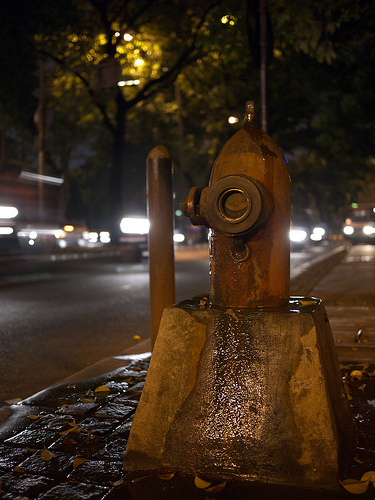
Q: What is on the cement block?
A: A rusted fire hydrant.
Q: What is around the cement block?
A: Water.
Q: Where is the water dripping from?
A: The cement block.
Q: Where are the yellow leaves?
A: On the sidewalk.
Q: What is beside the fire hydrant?
A: The street.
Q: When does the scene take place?
A: At night time.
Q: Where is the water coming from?
A: The fire hydrant.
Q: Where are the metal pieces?
A: On the fire hydrant.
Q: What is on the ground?
A: Yellow leaves.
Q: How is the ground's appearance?
A: Wet.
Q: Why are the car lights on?
A: Dark outside.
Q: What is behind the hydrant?
A: A metal pole.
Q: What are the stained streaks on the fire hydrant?
A: Water leaking on to base of fire hydrant.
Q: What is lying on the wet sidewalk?
A: Yellow leaves.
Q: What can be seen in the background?
A: Lights from businesses.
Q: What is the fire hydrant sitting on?
A: A cement base.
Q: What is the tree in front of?
A: Business signs.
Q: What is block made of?
A: Cement.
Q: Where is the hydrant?
A: On block.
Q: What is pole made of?
A: Metal.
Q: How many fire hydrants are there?
A: One.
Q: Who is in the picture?
A: Nobody.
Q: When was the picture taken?
A: At night.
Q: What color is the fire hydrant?
A: Yellow.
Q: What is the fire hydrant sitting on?
A: A block.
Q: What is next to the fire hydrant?
A: A pole.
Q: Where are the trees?
A: Behind the fire hydrant.